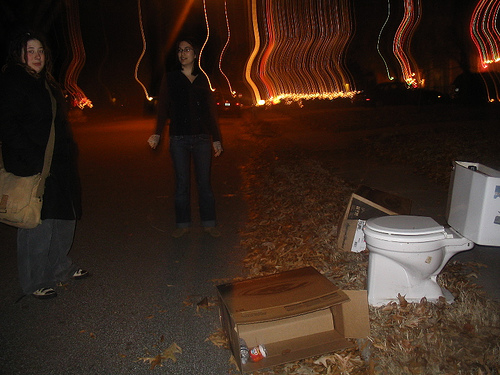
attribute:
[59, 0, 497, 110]
lights — orange, Red, background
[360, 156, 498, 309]
toilet — white,  white, broken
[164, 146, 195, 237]
jeans — blue 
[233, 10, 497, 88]
light — wavy, orange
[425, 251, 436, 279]
spot — tan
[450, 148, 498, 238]
toilet — tank , no top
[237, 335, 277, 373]
trash — inside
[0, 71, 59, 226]
bag — tan, messenger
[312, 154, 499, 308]
toilet — white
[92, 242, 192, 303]
road — side 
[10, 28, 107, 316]
woman — tall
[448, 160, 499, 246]
tank — white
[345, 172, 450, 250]
seat lid — closed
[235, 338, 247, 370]
bottle — plastic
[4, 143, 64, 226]
bag — large, canvas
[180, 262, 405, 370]
box — cardboard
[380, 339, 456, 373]
leaves — brown 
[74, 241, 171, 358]
road — side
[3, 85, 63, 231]
purse — brown 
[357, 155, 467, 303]
toilet — white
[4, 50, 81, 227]
person — female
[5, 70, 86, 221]
coat — black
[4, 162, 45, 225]
bag — brown